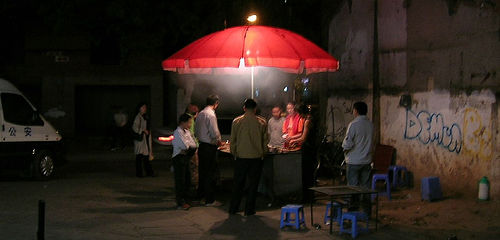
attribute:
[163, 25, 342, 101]
umbrella — large, open, red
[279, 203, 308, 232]
stool — blue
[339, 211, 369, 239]
stool — blue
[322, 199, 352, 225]
stool — blue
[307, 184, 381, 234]
black table — small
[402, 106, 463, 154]
graffiti — blue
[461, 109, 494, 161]
graffiti — yellow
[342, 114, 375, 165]
jacket — gray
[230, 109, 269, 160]
jacket — tan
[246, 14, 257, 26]
light — yellow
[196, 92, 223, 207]
person — standing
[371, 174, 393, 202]
chair — small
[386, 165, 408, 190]
chair — small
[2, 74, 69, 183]
van — black, white, withe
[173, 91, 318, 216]
people — standing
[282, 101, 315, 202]
two people — standing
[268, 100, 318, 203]
three people — standing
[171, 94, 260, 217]
four people — standing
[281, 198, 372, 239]
small stools — three, blue